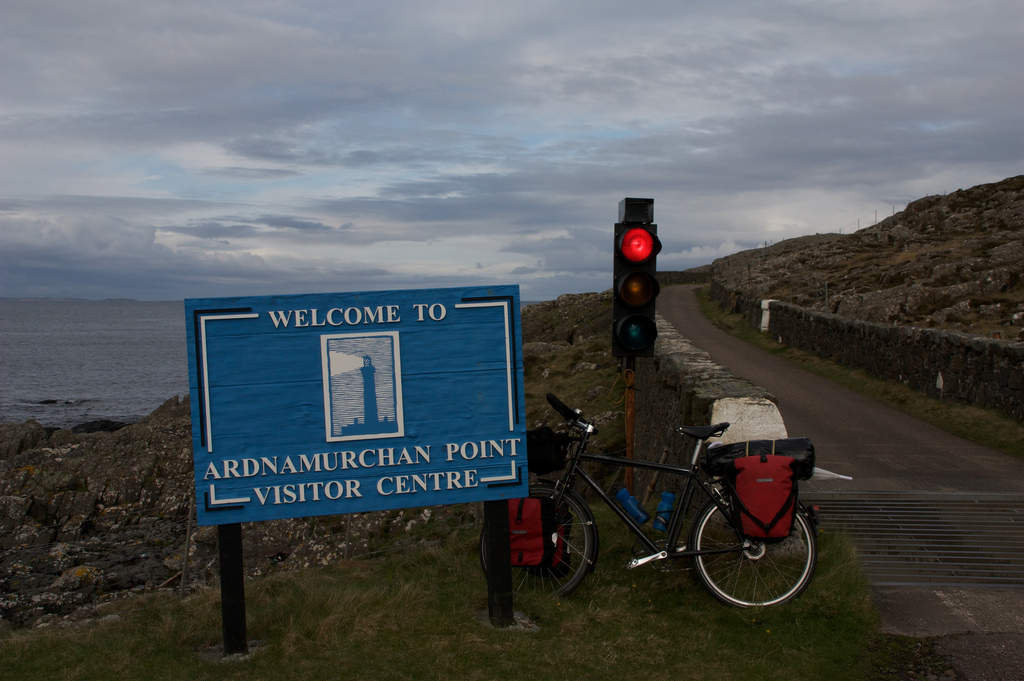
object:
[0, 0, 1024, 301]
sky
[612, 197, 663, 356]
traffic light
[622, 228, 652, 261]
red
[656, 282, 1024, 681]
road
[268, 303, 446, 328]
white writing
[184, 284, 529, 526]
blue background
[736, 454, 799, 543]
bag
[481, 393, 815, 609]
bicycle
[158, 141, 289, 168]
cloud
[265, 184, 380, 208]
cloud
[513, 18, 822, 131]
cloud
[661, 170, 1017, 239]
cloud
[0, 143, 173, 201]
cloud